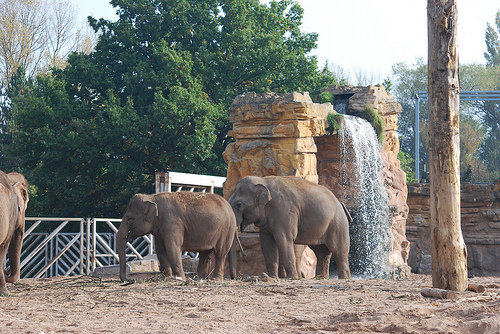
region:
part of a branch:
[111, 118, 131, 135]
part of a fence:
[68, 249, 83, 264]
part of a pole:
[423, 197, 471, 274]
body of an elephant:
[299, 210, 311, 222]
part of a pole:
[440, 230, 443, 260]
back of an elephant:
[184, 187, 199, 225]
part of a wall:
[384, 140, 416, 171]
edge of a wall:
[288, 98, 305, 150]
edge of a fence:
[66, 230, 94, 248]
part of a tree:
[478, 134, 489, 144]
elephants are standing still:
[108, 143, 375, 301]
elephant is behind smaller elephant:
[233, 159, 384, 304]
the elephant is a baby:
[104, 173, 254, 290]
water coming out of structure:
[310, 100, 415, 292]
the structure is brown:
[218, 53, 434, 274]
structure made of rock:
[235, 82, 407, 272]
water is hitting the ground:
[330, 103, 430, 305]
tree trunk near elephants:
[409, 8, 497, 320]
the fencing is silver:
[15, 218, 172, 283]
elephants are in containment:
[2, 140, 389, 309]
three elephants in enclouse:
[5, 161, 367, 288]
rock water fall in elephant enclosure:
[231, 76, 408, 273]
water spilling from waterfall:
[323, 113, 408, 271]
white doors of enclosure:
[20, 213, 157, 270]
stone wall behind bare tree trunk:
[405, 181, 499, 266]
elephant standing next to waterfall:
[234, 168, 359, 274]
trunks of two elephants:
[98, 215, 265, 280]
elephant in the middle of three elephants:
[102, 181, 246, 285]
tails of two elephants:
[234, 198, 359, 253]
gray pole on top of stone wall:
[408, 93, 431, 183]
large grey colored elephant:
[230, 174, 355, 276]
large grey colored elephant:
[116, 190, 241, 280]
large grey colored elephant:
[2, 169, 32, 289]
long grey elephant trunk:
[113, 225, 135, 282]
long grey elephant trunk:
[228, 219, 237, 271]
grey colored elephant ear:
[255, 183, 270, 208]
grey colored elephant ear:
[143, 198, 159, 223]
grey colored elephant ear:
[11, 177, 30, 211]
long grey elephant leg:
[270, 215, 298, 273]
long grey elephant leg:
[326, 217, 351, 279]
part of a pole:
[459, 243, 467, 257]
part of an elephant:
[306, 198, 321, 218]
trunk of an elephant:
[117, 232, 134, 275]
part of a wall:
[386, 213, 395, 227]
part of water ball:
[358, 196, 363, 204]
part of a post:
[54, 230, 70, 247]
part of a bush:
[81, 172, 98, 194]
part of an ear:
[113, 238, 139, 256]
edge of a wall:
[298, 135, 309, 190]